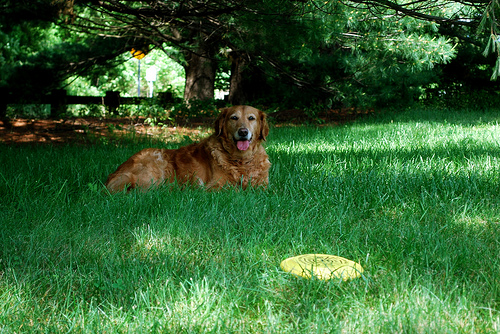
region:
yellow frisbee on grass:
[276, 237, 368, 290]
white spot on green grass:
[127, 222, 212, 270]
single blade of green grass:
[37, 174, 77, 202]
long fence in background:
[76, 84, 186, 111]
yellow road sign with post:
[116, 38, 176, 69]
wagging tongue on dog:
[231, 141, 261, 163]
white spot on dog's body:
[120, 150, 183, 201]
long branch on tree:
[352, 27, 470, 82]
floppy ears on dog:
[207, 98, 289, 150]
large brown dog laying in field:
[98, 108, 322, 210]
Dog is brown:
[92, 93, 293, 203]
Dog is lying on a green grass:
[94, 99, 285, 209]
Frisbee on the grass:
[271, 241, 371, 291]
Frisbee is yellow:
[275, 246, 370, 293]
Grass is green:
[1, 116, 496, 326]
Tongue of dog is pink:
[230, 135, 252, 152]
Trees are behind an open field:
[0, 2, 498, 113]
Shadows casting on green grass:
[293, 120, 493, 185]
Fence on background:
[5, 81, 181, 117]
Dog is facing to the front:
[104, 93, 294, 198]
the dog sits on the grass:
[104, 104, 269, 196]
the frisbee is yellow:
[282, 252, 360, 282]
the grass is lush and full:
[0, 117, 499, 323]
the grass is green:
[7, 120, 499, 331]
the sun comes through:
[6, 120, 499, 332]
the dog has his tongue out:
[237, 139, 250, 149]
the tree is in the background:
[181, 0, 215, 110]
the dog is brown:
[101, 103, 269, 194]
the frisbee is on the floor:
[281, 253, 366, 281]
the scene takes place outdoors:
[0, 0, 497, 332]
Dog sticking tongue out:
[101, 91, 279, 201]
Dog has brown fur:
[91, 100, 281, 200]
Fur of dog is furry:
[94, 97, 279, 199]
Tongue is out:
[231, 136, 249, 151]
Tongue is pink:
[232, 135, 249, 155]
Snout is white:
[231, 125, 251, 140]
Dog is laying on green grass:
[96, 95, 284, 200]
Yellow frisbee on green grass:
[275, 240, 370, 282]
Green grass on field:
[12, 120, 497, 330]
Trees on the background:
[8, 0, 487, 103]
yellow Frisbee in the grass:
[263, 244, 385, 290]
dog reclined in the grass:
[97, 100, 279, 203]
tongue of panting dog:
[233, 133, 259, 153]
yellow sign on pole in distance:
[127, 37, 154, 98]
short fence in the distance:
[53, 86, 185, 117]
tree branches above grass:
[371, 5, 483, 28]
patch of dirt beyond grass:
[8, 116, 198, 143]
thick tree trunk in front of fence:
[173, 45, 225, 112]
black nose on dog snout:
[234, 123, 254, 140]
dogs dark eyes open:
[226, 111, 261, 124]